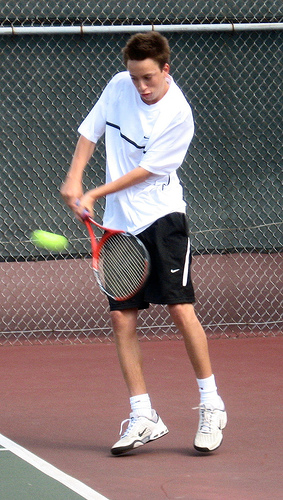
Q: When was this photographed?
A: Day time.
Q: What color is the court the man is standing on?
A: Red.